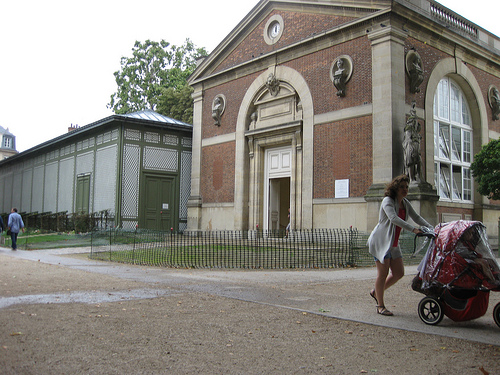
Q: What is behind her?
A: A man.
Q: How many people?
A: 2.